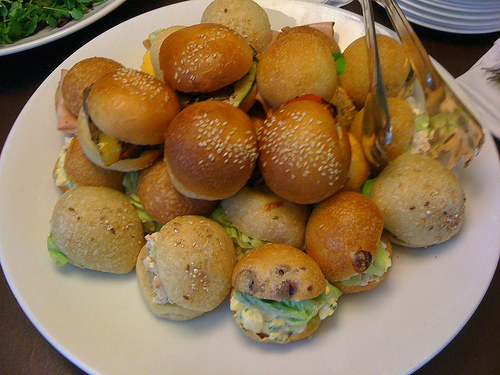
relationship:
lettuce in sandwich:
[233, 289, 340, 328] [234, 243, 332, 348]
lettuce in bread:
[343, 240, 394, 287] [302, 189, 392, 296]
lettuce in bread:
[47, 234, 68, 268] [48, 183, 143, 275]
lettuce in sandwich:
[124, 172, 163, 226] [130, 205, 237, 322]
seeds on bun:
[191, 114, 253, 171] [158, 108, 256, 200]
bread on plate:
[233, 243, 331, 341] [344, 268, 446, 364]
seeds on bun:
[191, 142, 211, 152] [163, 100, 258, 200]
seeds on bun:
[199, 118, 211, 131] [163, 100, 258, 200]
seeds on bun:
[213, 122, 223, 137] [163, 100, 258, 200]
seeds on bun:
[223, 140, 234, 160] [163, 100, 258, 200]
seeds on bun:
[227, 145, 243, 157] [163, 100, 258, 200]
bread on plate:
[87, 70, 177, 145] [4, 0, 496, 372]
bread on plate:
[87, 70, 177, 145] [0, 301, 488, 373]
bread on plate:
[258, 100, 350, 205] [34, 19, 462, 356]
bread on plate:
[161, 98, 257, 200] [34, 19, 462, 356]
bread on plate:
[158, 23, 255, 95] [34, 19, 462, 356]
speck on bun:
[105, 220, 117, 236] [50, 182, 135, 271]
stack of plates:
[429, 5, 466, 37] [391, 270, 464, 341]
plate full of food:
[4, 0, 496, 372] [54, 0, 467, 357]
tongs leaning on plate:
[357, 0, 483, 174] [4, 0, 496, 372]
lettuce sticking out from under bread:
[233, 289, 340, 328] [171, 97, 255, 189]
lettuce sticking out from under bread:
[343, 240, 404, 287] [162, 20, 248, 83]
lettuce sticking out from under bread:
[409, 95, 470, 145] [87, 70, 173, 137]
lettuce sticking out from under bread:
[208, 205, 268, 250] [382, 157, 463, 231]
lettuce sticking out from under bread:
[37, 225, 77, 271] [152, 217, 229, 299]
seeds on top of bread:
[258, 106, 346, 195] [233, 243, 331, 341]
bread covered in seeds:
[258, 100, 350, 205] [258, 106, 346, 195]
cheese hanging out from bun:
[95, 136, 120, 166] [73, 68, 181, 171]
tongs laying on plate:
[335, 13, 490, 174] [4, 0, 496, 372]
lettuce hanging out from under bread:
[233, 289, 340, 328] [215, 240, 348, 359]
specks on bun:
[254, 102, 344, 201] [187, 110, 311, 181]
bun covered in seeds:
[264, 97, 352, 206] [290, 129, 315, 163]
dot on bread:
[275, 278, 302, 299] [48, 183, 143, 275]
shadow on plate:
[231, 322, 316, 355] [4, 0, 496, 372]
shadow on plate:
[173, 302, 233, 334] [4, 0, 496, 372]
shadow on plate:
[346, 283, 392, 300] [4, 0, 496, 372]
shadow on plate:
[397, 236, 463, 260] [4, 0, 496, 372]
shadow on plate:
[55, 259, 134, 285] [4, 0, 496, 372]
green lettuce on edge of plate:
[3, 0, 89, 55] [5, 19, 90, 50]